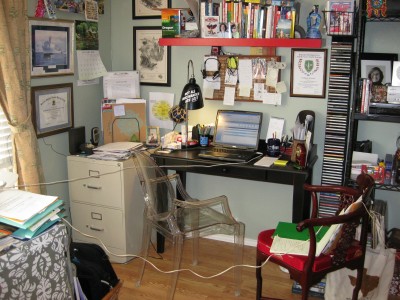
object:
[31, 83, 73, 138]
diploma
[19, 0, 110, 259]
wall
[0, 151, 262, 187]
cable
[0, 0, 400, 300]
room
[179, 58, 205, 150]
light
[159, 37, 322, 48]
shelf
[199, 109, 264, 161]
laptop